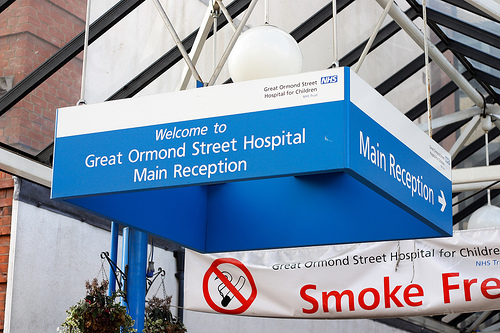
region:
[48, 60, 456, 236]
a blue and white sign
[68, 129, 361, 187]
the sign is for the hospital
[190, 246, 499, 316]
a banner is behind the sign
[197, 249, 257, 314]
a symbol is on the banner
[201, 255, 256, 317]
a no smoking symbol is on the banner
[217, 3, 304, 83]
a light hangs above the sign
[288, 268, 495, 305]
SMOKE FREE is in red text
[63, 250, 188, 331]
two flower baskets hang below the sign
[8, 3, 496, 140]
metal frame work is above the sign and light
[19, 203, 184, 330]
a white tarp is behind the hanging baskets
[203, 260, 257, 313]
a cigarette with a cross through it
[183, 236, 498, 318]
a banner about smoking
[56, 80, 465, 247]
a hanging welcome and direction sign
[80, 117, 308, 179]
welcoming words on the sign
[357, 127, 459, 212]
a direction to the reception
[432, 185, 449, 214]
a white arrow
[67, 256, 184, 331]
two hanging flower pots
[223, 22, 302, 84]
a round white light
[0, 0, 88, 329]
a brick wall behind the sign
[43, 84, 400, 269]
the sign is blue and white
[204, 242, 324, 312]
the sign is white with red writing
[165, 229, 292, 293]
the sign is a white banner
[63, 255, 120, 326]
bushes are hanging from a pole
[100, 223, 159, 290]
the pole is blue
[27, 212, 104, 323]
the wall is gray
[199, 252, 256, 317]
No sign on the cigarette.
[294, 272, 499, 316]
Red letters on the sign.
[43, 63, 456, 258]
box sign hanging from poles.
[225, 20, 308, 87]
round light globe above the sign.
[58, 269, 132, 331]
Hanging plant on the pole.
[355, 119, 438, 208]
White letters on the sign.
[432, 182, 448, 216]
White arrow on the sign.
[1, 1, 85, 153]
Brick on the building.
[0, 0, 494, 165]
Glass panels in the ceiling.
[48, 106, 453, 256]
blue coloring on the sign.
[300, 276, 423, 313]
the word smoke in red letters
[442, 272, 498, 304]
the letters Fre in red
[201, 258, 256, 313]
the sign for no smoking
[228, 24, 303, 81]
the light is large and circular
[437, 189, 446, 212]
the arrow is white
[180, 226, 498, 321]
the banner is white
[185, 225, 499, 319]
the banner for no smoking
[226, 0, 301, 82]
the light is hanging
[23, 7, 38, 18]
a brick in a wall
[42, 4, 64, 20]
a brick in a wall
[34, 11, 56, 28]
a brick in a wall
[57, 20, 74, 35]
a brick in a wall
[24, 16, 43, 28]
a brick in a wall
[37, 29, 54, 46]
a brick in a wall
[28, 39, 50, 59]
a brick in a wall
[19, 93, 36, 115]
a brick in a wall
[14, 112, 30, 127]
a brick in a wall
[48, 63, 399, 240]
a sign on the ceiling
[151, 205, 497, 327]
a smoke free sign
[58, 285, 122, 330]
a plant in the pot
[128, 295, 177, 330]
a plant in the pot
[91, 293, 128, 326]
green leaves on the plant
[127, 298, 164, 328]
green leaves on the pot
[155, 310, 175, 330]
green leaves on the plant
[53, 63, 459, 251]
a blue and white sign